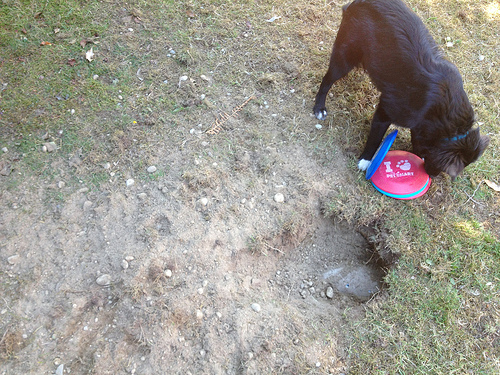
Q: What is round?
A: Frisbees.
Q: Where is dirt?
A: On the ground.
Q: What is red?
A: One frisbee.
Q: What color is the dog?
A: Black.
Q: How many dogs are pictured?
A: One.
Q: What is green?
A: Grass.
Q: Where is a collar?
A: Around dog's neck.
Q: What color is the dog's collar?
A: Blue.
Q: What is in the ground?
A: Hole.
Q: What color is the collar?
A: Blue.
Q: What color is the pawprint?
A: White.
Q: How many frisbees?
A: Four.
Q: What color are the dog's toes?
A: White.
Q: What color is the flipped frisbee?
A: Blue.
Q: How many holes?
A: One.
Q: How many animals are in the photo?
A: One.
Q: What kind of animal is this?
A: Dog.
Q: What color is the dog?
A: Black.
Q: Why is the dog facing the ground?
A: He's getting a frisbee.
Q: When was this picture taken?
A: Daytime.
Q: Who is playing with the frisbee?
A: A dog.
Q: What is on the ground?
A: Frisbees.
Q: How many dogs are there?
A: One.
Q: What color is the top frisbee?
A: Blue.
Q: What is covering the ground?
A: Grass.